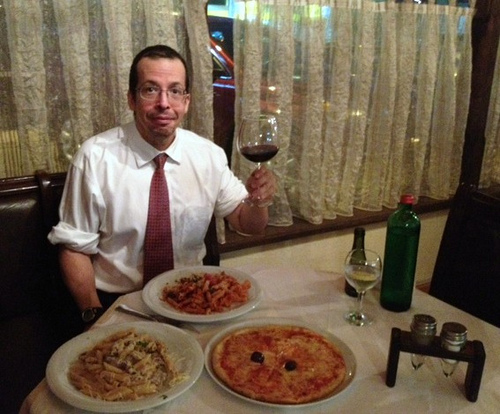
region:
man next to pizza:
[57, 26, 299, 210]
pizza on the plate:
[216, 297, 350, 411]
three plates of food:
[64, 246, 336, 407]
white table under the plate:
[276, 257, 326, 302]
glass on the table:
[342, 246, 395, 311]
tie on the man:
[123, 147, 179, 215]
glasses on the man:
[133, 82, 193, 118]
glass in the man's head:
[228, 133, 290, 176]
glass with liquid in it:
[225, 96, 306, 179]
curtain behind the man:
[301, 32, 386, 120]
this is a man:
[76, 61, 243, 251]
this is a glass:
[235, 110, 296, 149]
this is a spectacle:
[147, 84, 184, 99]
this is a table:
[288, 243, 341, 308]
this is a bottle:
[391, 209, 420, 294]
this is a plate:
[149, 389, 189, 409]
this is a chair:
[13, 177, 42, 309]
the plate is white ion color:
[186, 352, 203, 374]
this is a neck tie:
[148, 176, 176, 266]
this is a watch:
[77, 306, 104, 320]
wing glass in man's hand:
[235, 78, 335, 185]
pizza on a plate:
[248, 295, 344, 405]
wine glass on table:
[333, 240, 389, 305]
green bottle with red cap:
[375, 179, 441, 276]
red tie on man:
[120, 154, 187, 232]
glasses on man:
[117, 76, 205, 125]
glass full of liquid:
[223, 112, 297, 183]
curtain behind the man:
[274, 38, 391, 166]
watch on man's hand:
[73, 296, 105, 336]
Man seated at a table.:
[60, 45, 286, 311]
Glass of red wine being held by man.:
[236, 101, 277, 207]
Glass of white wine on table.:
[340, 250, 385, 333]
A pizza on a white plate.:
[202, 310, 362, 401]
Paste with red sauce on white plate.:
[143, 261, 268, 321]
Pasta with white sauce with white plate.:
[42, 325, 209, 406]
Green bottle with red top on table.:
[380, 178, 420, 318]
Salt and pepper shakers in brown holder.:
[380, 310, 487, 398]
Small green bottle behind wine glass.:
[340, 220, 368, 305]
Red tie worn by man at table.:
[133, 154, 177, 277]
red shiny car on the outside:
[200, 23, 239, 57]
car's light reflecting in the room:
[340, 95, 406, 152]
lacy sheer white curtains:
[328, 43, 415, 111]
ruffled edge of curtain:
[293, 197, 375, 228]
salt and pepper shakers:
[411, 310, 476, 366]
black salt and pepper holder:
[370, 307, 492, 394]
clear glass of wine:
[312, 231, 388, 321]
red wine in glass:
[230, 100, 292, 168]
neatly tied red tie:
[118, 135, 190, 285]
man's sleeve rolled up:
[15, 210, 118, 255]